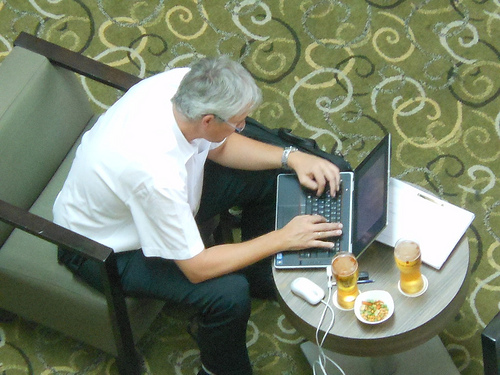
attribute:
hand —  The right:
[291, 152, 348, 193]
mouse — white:
[288, 268, 329, 308]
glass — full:
[390, 239, 430, 297]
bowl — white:
[357, 290, 394, 325]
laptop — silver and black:
[272, 135, 404, 268]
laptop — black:
[271, 129, 395, 272]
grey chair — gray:
[0, 45, 135, 369]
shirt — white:
[14, 82, 215, 239]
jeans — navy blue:
[55, 157, 287, 372]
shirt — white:
[50, 62, 229, 264]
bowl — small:
[350, 288, 396, 326]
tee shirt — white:
[51, 67, 229, 261]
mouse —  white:
[284, 275, 329, 305]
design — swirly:
[4, 1, 495, 373]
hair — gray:
[170, 48, 265, 125]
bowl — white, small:
[350, 284, 397, 324]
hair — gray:
[177, 46, 267, 126]